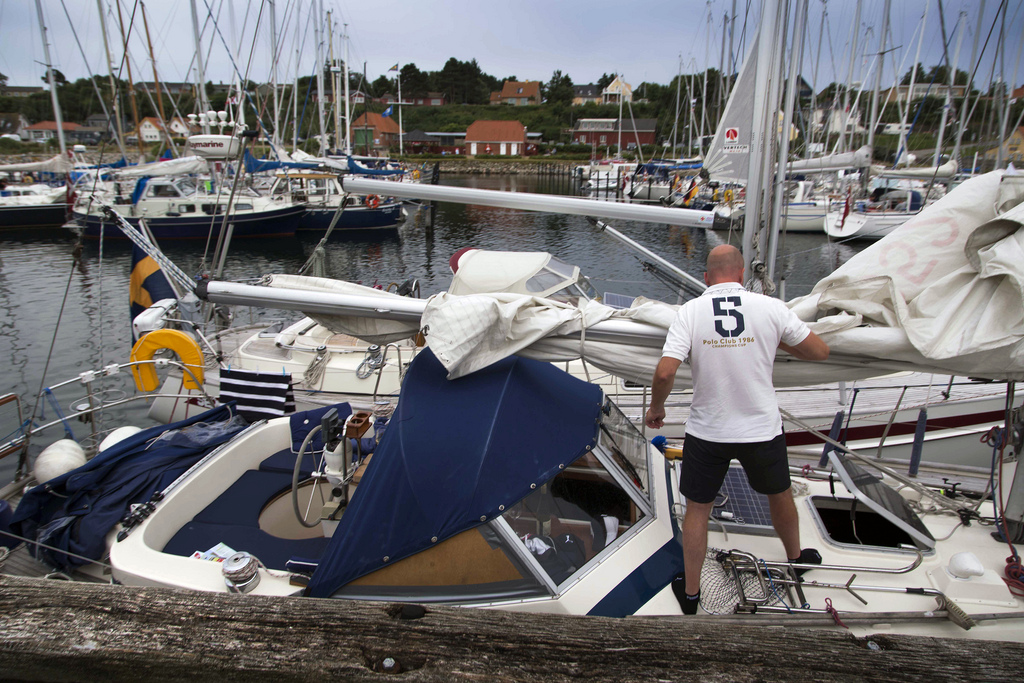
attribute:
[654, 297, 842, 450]
shirt — white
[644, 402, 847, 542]
shorts — black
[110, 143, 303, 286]
boat — blue, white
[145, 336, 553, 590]
boat — blue, white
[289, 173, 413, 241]
boat — white, blue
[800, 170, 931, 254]
boat — white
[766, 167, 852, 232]
boat — white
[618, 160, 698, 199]
boat — white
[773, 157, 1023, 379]
sail — white 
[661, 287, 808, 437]
polo — white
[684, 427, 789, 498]
shorts — black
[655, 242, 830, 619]
man — standing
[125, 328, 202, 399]
floaters — gold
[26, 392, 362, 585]
interior — navy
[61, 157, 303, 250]
boat — blue, white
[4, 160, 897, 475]
water — still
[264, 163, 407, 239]
boat — white, blue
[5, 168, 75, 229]
boat — blue, white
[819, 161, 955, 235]
boat — white, blue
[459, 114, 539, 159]
building — small, brick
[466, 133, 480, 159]
window — white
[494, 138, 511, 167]
window — white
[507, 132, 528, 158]
window — white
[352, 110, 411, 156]
building — small, brick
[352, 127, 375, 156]
door — large, green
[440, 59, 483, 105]
trees — full, green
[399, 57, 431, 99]
tree — green, full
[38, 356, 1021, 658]
white boat — blue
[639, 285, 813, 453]
shirt — man's shirt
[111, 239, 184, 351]
blue flag — yellow